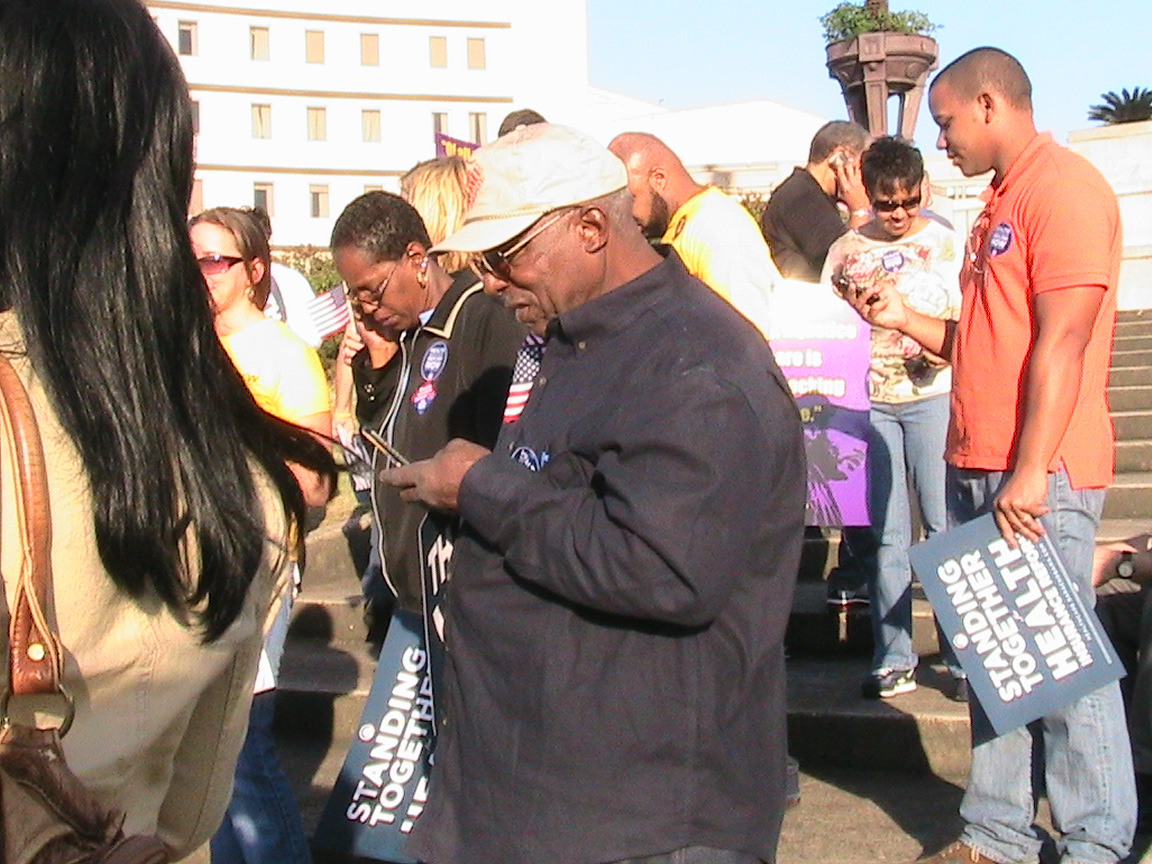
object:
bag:
[0, 358, 186, 864]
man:
[608, 132, 783, 363]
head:
[606, 132, 695, 238]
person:
[0, 0, 374, 864]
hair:
[0, 0, 376, 646]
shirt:
[943, 136, 1120, 494]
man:
[835, 44, 1142, 864]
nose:
[480, 270, 508, 297]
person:
[362, 124, 809, 864]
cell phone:
[362, 427, 412, 467]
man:
[831, 47, 1139, 864]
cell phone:
[831, 263, 881, 303]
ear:
[977, 93, 995, 124]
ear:
[574, 203, 608, 254]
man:
[378, 124, 803, 864]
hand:
[378, 437, 491, 510]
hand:
[833, 279, 907, 330]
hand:
[992, 468, 1049, 550]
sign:
[907, 506, 1129, 735]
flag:
[503, 330, 547, 423]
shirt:
[395, 242, 811, 861]